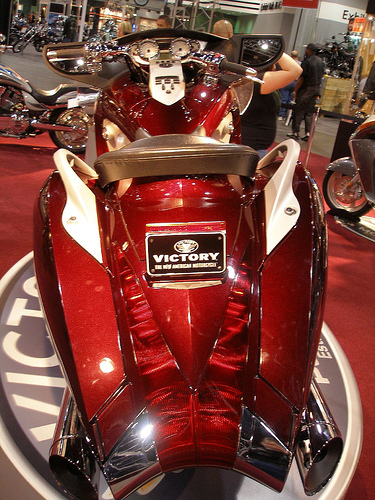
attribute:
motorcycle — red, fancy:
[32, 19, 329, 480]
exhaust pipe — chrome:
[298, 418, 344, 499]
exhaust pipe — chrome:
[43, 405, 104, 498]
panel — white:
[130, 36, 208, 63]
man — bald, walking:
[213, 15, 241, 39]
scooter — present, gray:
[3, 68, 91, 154]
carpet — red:
[4, 155, 36, 233]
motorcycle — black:
[12, 27, 52, 55]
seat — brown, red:
[113, 136, 244, 171]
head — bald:
[211, 19, 234, 40]